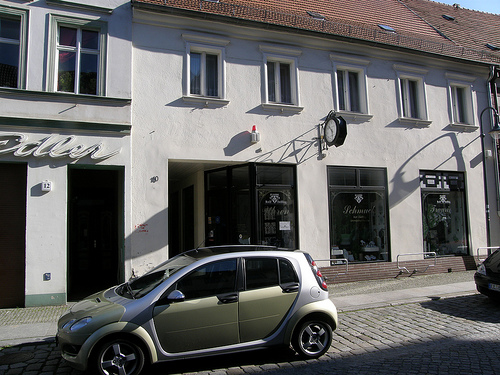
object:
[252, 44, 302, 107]
window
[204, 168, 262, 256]
doorway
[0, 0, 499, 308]
building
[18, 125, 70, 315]
wall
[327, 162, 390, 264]
window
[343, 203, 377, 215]
windowwriting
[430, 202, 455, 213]
windowwriting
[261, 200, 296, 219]
windowwriting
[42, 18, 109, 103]
window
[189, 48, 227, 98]
window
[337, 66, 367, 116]
window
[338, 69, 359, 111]
window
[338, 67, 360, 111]
black window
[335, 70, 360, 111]
glass window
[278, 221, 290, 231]
sign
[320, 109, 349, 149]
clock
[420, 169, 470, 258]
window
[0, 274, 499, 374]
brick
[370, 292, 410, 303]
ground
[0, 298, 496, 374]
road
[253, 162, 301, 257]
window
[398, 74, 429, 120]
window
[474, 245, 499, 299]
car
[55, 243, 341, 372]
car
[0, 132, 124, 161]
sign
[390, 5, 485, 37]
shingles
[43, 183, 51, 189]
number 12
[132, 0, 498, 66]
roof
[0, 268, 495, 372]
street